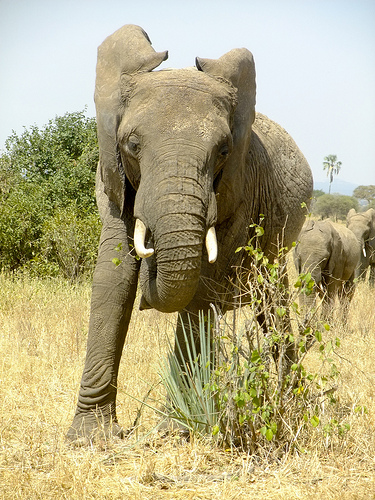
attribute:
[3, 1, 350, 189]
sky — blue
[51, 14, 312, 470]
elephant — large, gray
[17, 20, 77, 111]
clouds — white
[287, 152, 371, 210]
mountain — hazy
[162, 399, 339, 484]
grass — brown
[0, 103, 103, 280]
leaves — green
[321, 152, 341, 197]
palm tree — tall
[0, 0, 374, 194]
sky — blue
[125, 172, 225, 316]
elephant trunk — curled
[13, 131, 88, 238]
plant — spikey, green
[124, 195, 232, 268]
elephant tusk — white 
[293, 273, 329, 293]
elephant tusk — white 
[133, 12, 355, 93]
clouds — white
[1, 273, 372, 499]
grass — tall, dried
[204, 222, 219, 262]
tusk — white, ivory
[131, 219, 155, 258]
tusk — white, ivory